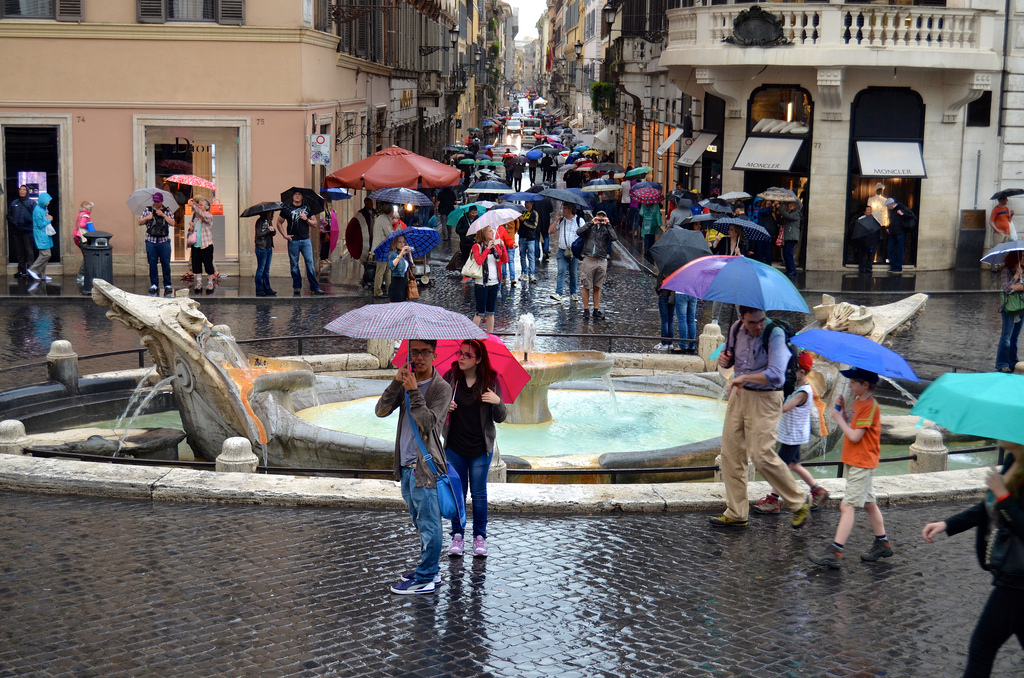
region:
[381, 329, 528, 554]
Woman holding pink umbrella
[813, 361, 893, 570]
Little boy wearing orange shirt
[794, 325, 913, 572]
Little boy holding blue umbrella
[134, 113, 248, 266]
Dior sign on window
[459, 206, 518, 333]
Woman holding white umbrella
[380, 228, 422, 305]
Woman taking a picture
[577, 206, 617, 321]
Man taking a picture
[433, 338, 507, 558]
Girl wearing pink sneakers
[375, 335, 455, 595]
Man talking on phone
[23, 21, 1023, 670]
picture taken during the day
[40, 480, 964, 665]
the day is raining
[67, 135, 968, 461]
umbrellas are open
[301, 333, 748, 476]
a fountain is turned on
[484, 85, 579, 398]
people are walking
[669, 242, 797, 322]
multi-colored umbrella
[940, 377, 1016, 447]
a green umbrella is open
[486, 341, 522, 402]
a pink umbrella is open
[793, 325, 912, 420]
boy holds blue umbrella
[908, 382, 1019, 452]
umbrella is light green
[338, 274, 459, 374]
boy holds purple umbrella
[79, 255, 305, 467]
brown sculpture in pool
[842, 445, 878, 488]
boy has tan shorts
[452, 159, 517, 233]
People covered in umbrellas on the street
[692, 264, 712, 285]
The wet surface of an umbrella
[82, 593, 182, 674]
Surface laid with cobal stones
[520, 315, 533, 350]
Water spewing out of a fountain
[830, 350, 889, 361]
A boy under a blue umbrella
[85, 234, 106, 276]
A black trash bin on the side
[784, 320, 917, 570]
Boy in tan shorts holding blue umbrella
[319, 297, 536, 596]
Two people holding umbrellas in the rain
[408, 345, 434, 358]
Glasses on man's face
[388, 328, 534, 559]
Woman in pink shoes holding pink umbrella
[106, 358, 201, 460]
Water coming out of front of fountain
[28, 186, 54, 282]
Person in coat with blue hood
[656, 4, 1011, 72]
Balcony railing on side of building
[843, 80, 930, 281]
Entrance to front of building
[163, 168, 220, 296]
Person holding umbrella with pattern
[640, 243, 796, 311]
A man is holding a umbrella.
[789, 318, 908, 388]
A young boy is holding a blue umbrella.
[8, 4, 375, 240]
a peach colored building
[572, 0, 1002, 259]
a white building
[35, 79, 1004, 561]
people walking on the street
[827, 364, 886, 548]
a kid wearing an orange shirt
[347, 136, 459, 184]
a large red umbrella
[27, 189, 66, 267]
a person in a blue jacket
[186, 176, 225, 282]
a person with a red umbrella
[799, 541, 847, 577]
Grey shoe on a boy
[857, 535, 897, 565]
Shoe on a boy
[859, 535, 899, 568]
Grey shoe on a boy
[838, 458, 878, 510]
Shorts on a boy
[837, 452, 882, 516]
Tan shorts of a boy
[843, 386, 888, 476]
Shirt on a boy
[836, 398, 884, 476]
Orange shirt on a boy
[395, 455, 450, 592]
Blue jeans on a man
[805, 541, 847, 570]
Shoe on a boy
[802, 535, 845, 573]
Grey shoe on a boy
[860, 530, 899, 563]
Grey shoe on a boy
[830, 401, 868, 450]
Arm of a boy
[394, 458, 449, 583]
Jeans on a man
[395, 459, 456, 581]
Blue jeans on a man